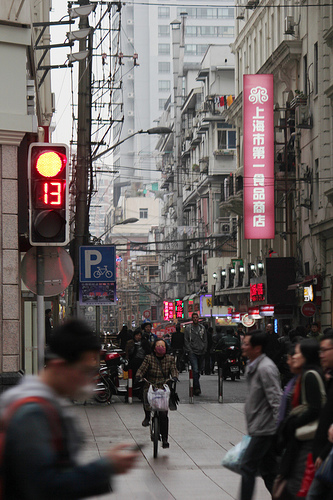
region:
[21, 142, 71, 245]
the traffic sign is red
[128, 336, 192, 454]
person on the bicycle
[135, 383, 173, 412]
the basket on the bicycle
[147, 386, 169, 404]
the bag in the basket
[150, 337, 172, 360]
the person wearing mask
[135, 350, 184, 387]
the person wearing plaid jacket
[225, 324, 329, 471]
people on the street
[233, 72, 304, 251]
the sign on the building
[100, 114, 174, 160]
the street light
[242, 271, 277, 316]
sign on building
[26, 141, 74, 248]
Illuminated traffic street sign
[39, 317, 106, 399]
Head of walking person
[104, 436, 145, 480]
Hand of walking person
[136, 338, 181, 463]
Person riding on bike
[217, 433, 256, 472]
Part of person's shopping bag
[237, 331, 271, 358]
Head of walking person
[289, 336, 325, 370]
Head of walking person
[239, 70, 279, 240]
Red and white business sign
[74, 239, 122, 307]
Blue and white information sign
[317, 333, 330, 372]
Head of walking person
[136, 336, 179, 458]
a woman riding a bicycle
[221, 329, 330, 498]
people walking on a sidewalk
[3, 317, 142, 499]
man walking and holding a cell phone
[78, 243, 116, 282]
a white and blue sign on a pole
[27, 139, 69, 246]
a pedestrian light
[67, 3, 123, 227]
telephone wires attached to a pole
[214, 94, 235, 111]
clothes hanging from a balcony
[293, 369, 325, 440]
woman holding a white purse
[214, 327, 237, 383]
man dressed in black on a moped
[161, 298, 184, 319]
neon sign over shop windows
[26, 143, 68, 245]
Cross walk street light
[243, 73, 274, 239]
Sign written in asian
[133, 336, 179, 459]
Woman riding a bike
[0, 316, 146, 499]
Man wearing mask walking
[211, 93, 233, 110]
Clothes hung up to dry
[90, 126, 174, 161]
Street light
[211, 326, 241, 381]
Man riding a motor bike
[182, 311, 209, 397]
Tall man walking down street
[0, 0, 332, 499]
crowded city in asia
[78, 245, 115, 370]
A parking sign for bikes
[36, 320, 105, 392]
head of a person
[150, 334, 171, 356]
head of a person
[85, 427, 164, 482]
hand of a person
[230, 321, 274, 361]
head of a person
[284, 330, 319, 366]
head of a person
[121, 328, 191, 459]
person riding bicycle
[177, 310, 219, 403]
tall person walking on street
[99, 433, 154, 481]
person holding a phone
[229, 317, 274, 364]
person with black hair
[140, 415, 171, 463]
front wheel of a bike